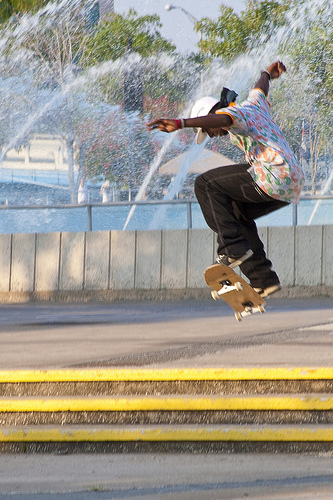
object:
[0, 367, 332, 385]
line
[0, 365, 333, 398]
step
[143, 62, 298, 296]
person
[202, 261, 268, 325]
skateboard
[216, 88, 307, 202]
shirt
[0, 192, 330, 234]
fence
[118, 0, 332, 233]
spout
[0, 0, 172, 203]
tree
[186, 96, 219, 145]
cap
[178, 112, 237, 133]
arm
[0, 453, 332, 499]
ground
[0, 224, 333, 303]
wall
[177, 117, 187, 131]
band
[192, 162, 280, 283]
pants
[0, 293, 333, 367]
sidewalk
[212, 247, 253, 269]
shoe